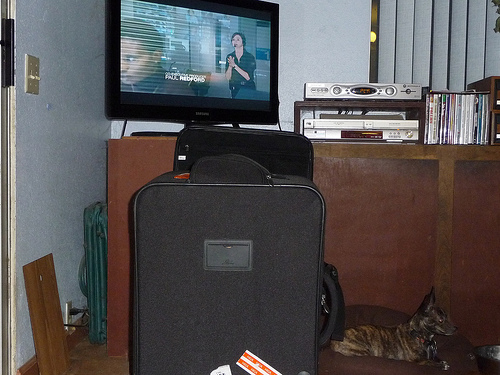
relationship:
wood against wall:
[12, 219, 81, 371] [18, 67, 140, 372]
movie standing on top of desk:
[446, 92, 455, 143] [111, 121, 485, 351]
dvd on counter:
[431, 95, 437, 145] [292, 116, 483, 177]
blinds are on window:
[373, 2, 491, 75] [362, 3, 488, 123]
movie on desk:
[431, 94, 439, 150] [103, 87, 485, 356]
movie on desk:
[471, 95, 477, 146] [103, 87, 485, 356]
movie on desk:
[471, 95, 477, 146] [97, 109, 492, 357]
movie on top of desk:
[446, 89, 469, 146] [111, 121, 485, 351]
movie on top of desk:
[460, 89, 481, 148] [107, 110, 491, 332]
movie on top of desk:
[463, 94, 487, 153] [111, 121, 485, 351]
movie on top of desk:
[474, 97, 490, 140] [109, 130, 499, 358]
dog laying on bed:
[341, 292, 450, 362] [321, 296, 436, 374]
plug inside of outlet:
[65, 296, 87, 327] [57, 290, 84, 333]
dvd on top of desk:
[294, 78, 423, 146] [105, 137, 499, 356]